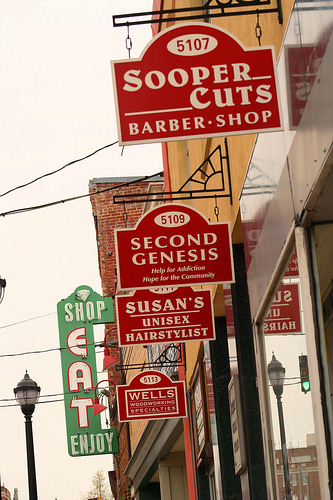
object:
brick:
[99, 212, 107, 216]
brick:
[97, 218, 107, 222]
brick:
[105, 193, 111, 196]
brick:
[101, 269, 108, 274]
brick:
[99, 239, 106, 245]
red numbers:
[160, 214, 168, 227]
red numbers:
[154, 375, 159, 381]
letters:
[66, 324, 88, 357]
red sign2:
[111, 200, 237, 296]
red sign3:
[113, 285, 216, 352]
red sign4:
[115, 367, 190, 422]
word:
[65, 321, 94, 434]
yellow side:
[119, 1, 294, 459]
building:
[88, 0, 333, 498]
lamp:
[13, 370, 42, 499]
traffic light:
[299, 351, 313, 394]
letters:
[130, 235, 142, 251]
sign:
[55, 281, 121, 459]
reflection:
[258, 245, 325, 498]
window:
[255, 240, 323, 499]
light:
[302, 378, 312, 390]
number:
[201, 35, 211, 50]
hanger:
[113, 135, 236, 208]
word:
[132, 246, 220, 269]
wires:
[0, 136, 119, 201]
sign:
[109, 19, 286, 148]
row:
[114, 1, 284, 423]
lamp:
[266, 349, 293, 498]